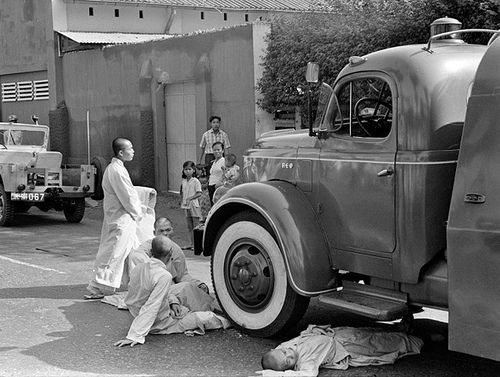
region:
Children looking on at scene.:
[172, 149, 254, 245]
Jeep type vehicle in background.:
[0, 106, 97, 230]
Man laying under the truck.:
[247, 316, 427, 373]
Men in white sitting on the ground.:
[111, 211, 229, 352]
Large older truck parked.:
[193, 8, 498, 364]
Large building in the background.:
[4, 3, 286, 198]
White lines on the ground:
[2, 245, 70, 280]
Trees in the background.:
[255, 3, 499, 128]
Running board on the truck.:
[318, 278, 423, 328]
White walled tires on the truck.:
[208, 211, 308, 336]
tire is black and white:
[252, 311, 264, 336]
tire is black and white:
[267, 307, 278, 339]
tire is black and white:
[259, 313, 276, 345]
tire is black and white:
[248, 295, 265, 328]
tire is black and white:
[274, 305, 292, 325]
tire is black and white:
[265, 277, 287, 315]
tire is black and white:
[246, 305, 262, 335]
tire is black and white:
[265, 298, 280, 323]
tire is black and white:
[244, 322, 264, 334]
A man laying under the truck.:
[251, 321, 382, 375]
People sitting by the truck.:
[136, 230, 251, 352]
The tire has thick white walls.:
[213, 206, 293, 346]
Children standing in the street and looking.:
[174, 143, 259, 226]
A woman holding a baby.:
[204, 140, 251, 181]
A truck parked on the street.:
[212, 48, 458, 352]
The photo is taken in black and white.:
[30, 14, 495, 371]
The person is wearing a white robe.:
[96, 128, 156, 287]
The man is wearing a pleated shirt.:
[182, 116, 244, 164]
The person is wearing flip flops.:
[66, 279, 131, 311]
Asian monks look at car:
[104, 128, 185, 355]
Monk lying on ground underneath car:
[253, 335, 435, 360]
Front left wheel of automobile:
[218, 212, 291, 328]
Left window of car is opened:
[325, 84, 400, 135]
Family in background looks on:
[171, 116, 236, 192]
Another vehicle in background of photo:
[5, 114, 96, 215]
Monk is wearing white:
[109, 159, 135, 286]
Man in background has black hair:
[210, 113, 222, 128]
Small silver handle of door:
[378, 166, 392, 179]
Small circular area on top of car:
[429, 12, 463, 34]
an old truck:
[184, 12, 499, 370]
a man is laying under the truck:
[186, 45, 475, 375]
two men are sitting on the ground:
[104, 211, 229, 349]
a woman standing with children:
[167, 137, 258, 247]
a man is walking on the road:
[81, 128, 173, 312]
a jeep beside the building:
[0, 102, 111, 243]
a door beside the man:
[135, 62, 228, 197]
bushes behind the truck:
[258, 0, 498, 232]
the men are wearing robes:
[81, 135, 452, 375]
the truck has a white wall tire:
[191, 190, 334, 337]